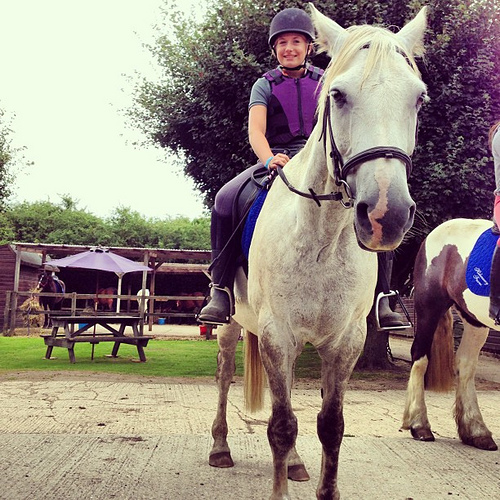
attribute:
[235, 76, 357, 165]
vest — black, purple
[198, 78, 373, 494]
horse — white, black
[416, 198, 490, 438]
horse — brown, white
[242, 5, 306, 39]
helmet — black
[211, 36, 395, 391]
horse — white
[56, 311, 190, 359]
bench — wooden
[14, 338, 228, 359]
grass — green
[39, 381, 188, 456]
cement — cracked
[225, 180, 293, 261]
blanket — blue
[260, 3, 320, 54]
helmet — black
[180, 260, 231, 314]
boots — black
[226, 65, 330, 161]
tshirt — gray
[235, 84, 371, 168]
vest — purple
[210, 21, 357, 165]
woman — riding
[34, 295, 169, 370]
table — wooden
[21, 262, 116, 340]
horse — brown, eating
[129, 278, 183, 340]
horse — white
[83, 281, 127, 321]
horse — brown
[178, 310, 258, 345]
bucket — red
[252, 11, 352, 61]
helmet — black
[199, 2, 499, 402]
horse — white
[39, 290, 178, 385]
table — wooden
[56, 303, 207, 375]
table — outdoors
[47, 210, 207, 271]
trees — green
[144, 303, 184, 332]
bucket — blue 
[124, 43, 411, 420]
horse — white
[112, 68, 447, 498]
horse — white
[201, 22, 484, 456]
horse — white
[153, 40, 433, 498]
horse — white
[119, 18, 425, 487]
horse — white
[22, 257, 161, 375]
table — Small , brown 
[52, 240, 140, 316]
umbrella — black , Large 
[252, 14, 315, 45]
helmet — Black